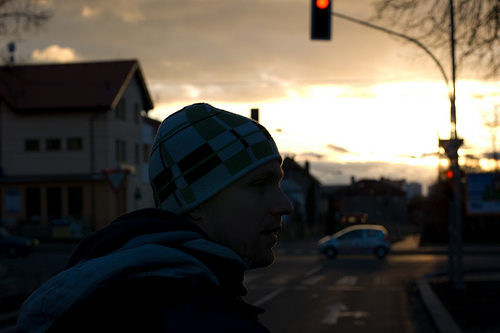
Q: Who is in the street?
A: The man.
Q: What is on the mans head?
A: The hat.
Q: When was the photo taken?
A: The evening.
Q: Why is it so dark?
A: Sun went down.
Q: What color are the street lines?
A: White.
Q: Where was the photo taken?
A: Close to a traffic light.